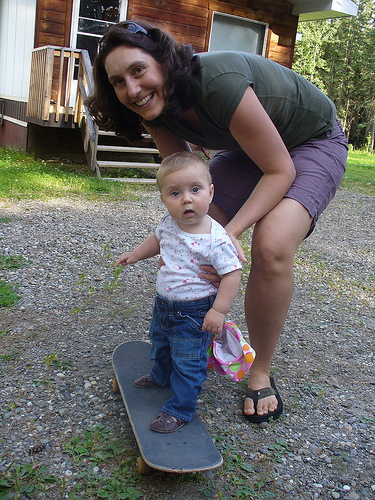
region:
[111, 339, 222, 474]
the skateboard under the baby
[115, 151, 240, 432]
the baby on the skateboard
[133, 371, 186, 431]
the shoes on the baby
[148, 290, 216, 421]
the pants on the baby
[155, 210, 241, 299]
the onesie on the baby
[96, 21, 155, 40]
the sunglasses on the woman's head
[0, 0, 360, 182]
the house behind the woman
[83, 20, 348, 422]
the woman holding the baby up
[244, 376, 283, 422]
the slipper on the woman's foot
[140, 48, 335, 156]
the shirt on the woman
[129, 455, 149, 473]
a wheel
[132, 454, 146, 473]
the wheel is yellow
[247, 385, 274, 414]
a sandal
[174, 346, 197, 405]
the child is wearing blue jeans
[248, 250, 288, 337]
the womens leg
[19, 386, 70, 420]
the rocks on the ground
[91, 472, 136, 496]
small patches of grass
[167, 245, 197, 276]
a shirt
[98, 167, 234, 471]
a small baby on a skateboard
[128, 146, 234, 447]
a baby wearing shoes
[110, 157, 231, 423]
a baby wearing blue jeans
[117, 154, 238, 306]
a baby wearing a flowered onesies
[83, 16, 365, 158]
a woman wearing a tshirt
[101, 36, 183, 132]
a woman smiling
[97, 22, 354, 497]
a woman wearing black sandals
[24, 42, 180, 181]
a wooden staircase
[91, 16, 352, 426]
Woman with a pair of glasses on her head.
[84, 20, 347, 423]
Woman with dark colored hair.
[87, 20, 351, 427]
Woman wearing a green shirt.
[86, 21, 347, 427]
Woman wearing a pair of shorts.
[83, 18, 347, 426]
Woman wearing sandals.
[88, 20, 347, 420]
Woman holding a young child on a skateboard.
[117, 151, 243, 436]
Small child wearing a white shirt.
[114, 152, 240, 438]
Small child wearing blue pants.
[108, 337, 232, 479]
Skateboard with a small child on it.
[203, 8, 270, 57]
Glass window.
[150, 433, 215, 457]
a skateboard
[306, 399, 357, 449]
small rocks on the ground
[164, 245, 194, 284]
a shirt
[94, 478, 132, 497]
green patches of plants in the ground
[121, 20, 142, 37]
black sunglasses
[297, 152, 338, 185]
shorts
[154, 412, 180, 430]
dark brown kids shoe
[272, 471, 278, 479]
small grey pebble by the skateboard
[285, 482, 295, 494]
small grey pebble by the skateboard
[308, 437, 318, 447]
small grey pebble by the skateboard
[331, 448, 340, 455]
small grey pebble by the skateboard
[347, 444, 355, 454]
small grey pebble by the skateboard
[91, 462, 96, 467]
small grey pebble by the skateboard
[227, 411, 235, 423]
small grey pebble by the skateboard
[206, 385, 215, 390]
small grey pebble by the skateboard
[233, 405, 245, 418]
small grey pebble by the skateboard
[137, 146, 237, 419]
baby wearing a tshirt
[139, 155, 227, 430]
baby wearing blue jeans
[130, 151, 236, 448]
baby wearing brown shoes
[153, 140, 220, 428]
baby standing on skate board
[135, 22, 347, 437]
woman holding baby on skate board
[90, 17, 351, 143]
woman wearing green shirt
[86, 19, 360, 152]
woman wearing shorts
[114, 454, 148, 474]
wheel of a skate board